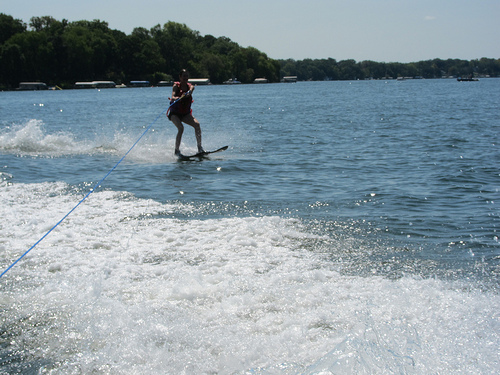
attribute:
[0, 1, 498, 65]
sky — blue, overcast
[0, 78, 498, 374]
water — clear, white, calm, blue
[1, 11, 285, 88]
trees — green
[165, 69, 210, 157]
person — water skiing, wakeboarding, wakeboarder, being pulled, female, wet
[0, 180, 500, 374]
wake — white, foamy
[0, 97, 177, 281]
cord — blue, for wakeboarding, tether cord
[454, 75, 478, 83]
boat — black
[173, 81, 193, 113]
vest — red, life jacket